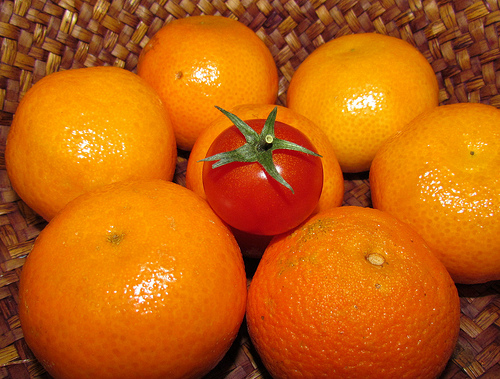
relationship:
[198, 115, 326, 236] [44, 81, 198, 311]
tomato and fruits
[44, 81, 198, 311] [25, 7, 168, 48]
fruits in basket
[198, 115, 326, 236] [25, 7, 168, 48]
tomato in basket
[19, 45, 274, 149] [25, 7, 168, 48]
oranges in basket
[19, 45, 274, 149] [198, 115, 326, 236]
oranges and tomato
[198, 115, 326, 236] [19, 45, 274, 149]
tomato on oranges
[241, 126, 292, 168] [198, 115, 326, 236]
stem on tomato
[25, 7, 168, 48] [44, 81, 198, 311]
basket has fruits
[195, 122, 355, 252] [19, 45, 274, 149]
tomato on oranges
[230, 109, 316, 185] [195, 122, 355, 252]
leaf on tomato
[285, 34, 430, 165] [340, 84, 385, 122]
orange has glare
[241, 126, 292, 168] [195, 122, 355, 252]
stem on tomato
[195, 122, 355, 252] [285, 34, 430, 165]
tomato on orange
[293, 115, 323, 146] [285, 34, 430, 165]
spot on orange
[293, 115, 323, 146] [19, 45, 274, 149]
spot on oranges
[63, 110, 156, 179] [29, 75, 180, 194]
shine on orange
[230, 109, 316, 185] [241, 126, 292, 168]
leaf on stem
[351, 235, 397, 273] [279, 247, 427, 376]
hole on orange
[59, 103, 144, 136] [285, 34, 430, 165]
grooves on orange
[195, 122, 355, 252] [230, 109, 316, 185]
tomato has leaf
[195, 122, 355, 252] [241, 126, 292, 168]
tomato has stem